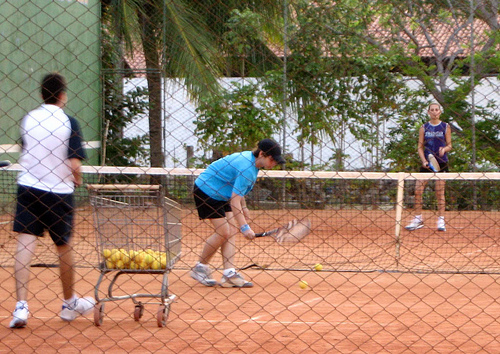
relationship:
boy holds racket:
[187, 135, 285, 289] [248, 202, 310, 250]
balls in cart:
[100, 241, 175, 275] [65, 201, 193, 311]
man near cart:
[13, 71, 83, 322] [65, 201, 193, 311]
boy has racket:
[188, 124, 299, 291] [248, 202, 310, 250]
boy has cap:
[188, 124, 299, 291] [251, 129, 289, 171]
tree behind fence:
[99, 2, 283, 177] [315, 9, 495, 82]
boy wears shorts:
[187, 135, 285, 289] [185, 190, 240, 235]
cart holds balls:
[65, 201, 193, 311] [100, 241, 175, 275]